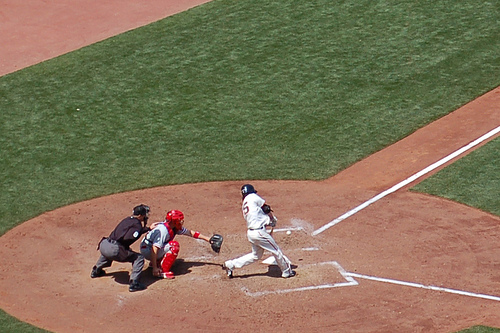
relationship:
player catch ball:
[135, 203, 228, 286] [284, 226, 292, 237]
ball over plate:
[284, 226, 292, 237] [262, 250, 293, 268]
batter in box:
[216, 178, 297, 281] [214, 220, 363, 300]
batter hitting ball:
[216, 178, 297, 281] [284, 226, 292, 237]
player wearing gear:
[135, 203, 228, 286] [163, 209, 182, 282]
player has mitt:
[135, 203, 228, 286] [208, 232, 228, 255]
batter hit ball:
[216, 178, 297, 281] [284, 226, 292, 237]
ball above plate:
[284, 226, 292, 237] [262, 250, 293, 268]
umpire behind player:
[85, 199, 160, 300] [135, 203, 228, 286]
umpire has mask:
[85, 199, 160, 300] [132, 202, 152, 225]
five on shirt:
[241, 201, 252, 216] [238, 192, 271, 230]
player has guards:
[135, 203, 228, 286] [161, 240, 180, 274]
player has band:
[135, 203, 228, 286] [192, 230, 200, 241]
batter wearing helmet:
[216, 178, 297, 281] [238, 181, 260, 197]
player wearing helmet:
[135, 203, 228, 286] [163, 208, 185, 238]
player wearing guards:
[135, 203, 228, 286] [161, 240, 180, 274]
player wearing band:
[135, 203, 228, 286] [192, 230, 200, 241]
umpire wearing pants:
[85, 199, 160, 300] [86, 236, 147, 285]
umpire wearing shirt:
[85, 199, 160, 300] [102, 214, 150, 251]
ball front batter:
[284, 226, 292, 237] [216, 178, 297, 281]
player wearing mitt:
[135, 203, 228, 286] [208, 232, 228, 255]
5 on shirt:
[241, 201, 252, 216] [238, 192, 271, 230]